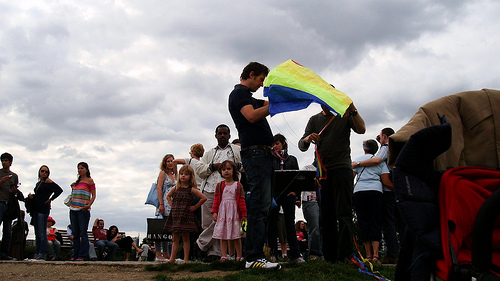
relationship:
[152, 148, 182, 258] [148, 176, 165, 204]
woman carries bag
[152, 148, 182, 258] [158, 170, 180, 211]
woman wears dress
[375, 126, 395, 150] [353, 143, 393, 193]
man wears shirts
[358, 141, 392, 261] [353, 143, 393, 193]
woman wears shirts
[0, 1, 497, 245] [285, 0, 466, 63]
sky contains clouds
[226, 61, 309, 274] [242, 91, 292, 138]
man wears shirt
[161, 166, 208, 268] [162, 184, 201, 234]
girl wears dress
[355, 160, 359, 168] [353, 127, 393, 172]
watch on man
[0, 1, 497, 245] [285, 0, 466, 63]
sky has clouds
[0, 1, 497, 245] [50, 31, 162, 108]
sky has clouds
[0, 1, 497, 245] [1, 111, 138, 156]
sky has clouds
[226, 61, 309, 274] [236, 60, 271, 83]
man has hair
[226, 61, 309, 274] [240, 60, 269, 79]
man has hair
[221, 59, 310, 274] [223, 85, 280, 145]
man wearing shirt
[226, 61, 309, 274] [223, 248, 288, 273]
man wearing shoes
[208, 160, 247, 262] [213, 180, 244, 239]
girl wearing dress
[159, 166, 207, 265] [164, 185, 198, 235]
girl wearing dress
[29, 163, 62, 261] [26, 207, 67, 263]
blackshirt woman wearing jeans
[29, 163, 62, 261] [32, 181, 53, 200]
blackshirt woman wearing black t-shirt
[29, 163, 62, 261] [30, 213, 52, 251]
blackshirt woman wearing black pants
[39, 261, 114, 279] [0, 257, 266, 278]
ground has sand